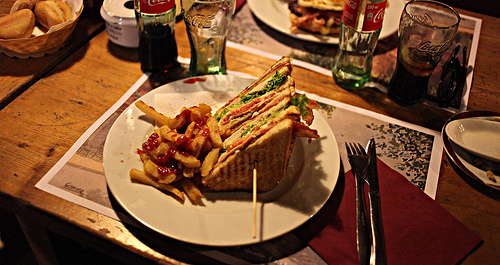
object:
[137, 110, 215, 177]
ketchup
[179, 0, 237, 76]
glass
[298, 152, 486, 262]
napkin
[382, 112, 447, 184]
paper placemat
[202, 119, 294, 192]
bread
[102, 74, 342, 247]
plate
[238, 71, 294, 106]
lettuce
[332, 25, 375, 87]
soda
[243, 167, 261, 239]
stick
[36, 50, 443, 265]
mat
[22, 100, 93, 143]
damage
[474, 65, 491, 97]
damage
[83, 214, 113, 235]
damage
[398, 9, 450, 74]
glass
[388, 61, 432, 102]
coke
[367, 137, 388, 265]
knife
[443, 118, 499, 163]
plate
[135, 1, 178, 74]
bottle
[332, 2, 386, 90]
bottle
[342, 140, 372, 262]
fork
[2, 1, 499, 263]
table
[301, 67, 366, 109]
ground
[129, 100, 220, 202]
fries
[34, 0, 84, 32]
roll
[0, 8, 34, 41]
roll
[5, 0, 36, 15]
roll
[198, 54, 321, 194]
sandwich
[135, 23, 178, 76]
coke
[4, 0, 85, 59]
basket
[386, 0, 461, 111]
cup